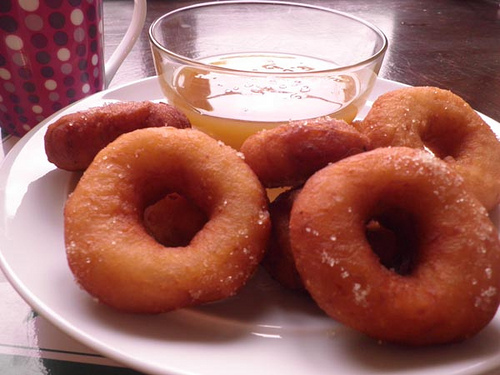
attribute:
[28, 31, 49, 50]
polka dot — mauve, purple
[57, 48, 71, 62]
polka dot — white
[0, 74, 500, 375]
plate — white, round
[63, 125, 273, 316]
donut — light brown, showing, deep brown, golden brown, sugar coated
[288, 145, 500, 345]
donut — showing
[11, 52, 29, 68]
polka dot — pink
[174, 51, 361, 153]
sauce — dipping sauce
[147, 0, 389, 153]
bowl — glass, small, half full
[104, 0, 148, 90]
handle — white